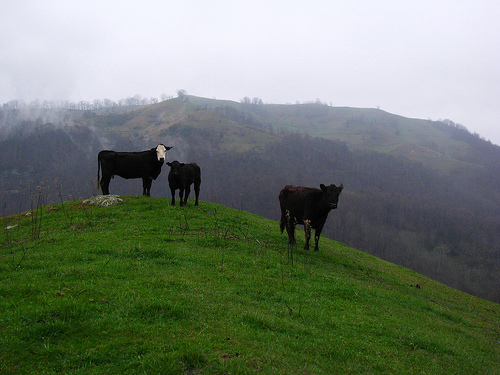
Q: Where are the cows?
A: Mountains.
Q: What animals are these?
A: Cows.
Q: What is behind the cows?
A: Mountain.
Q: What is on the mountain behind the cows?
A: Trees.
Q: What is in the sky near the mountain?
A: Fog.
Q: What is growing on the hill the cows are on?
A: Grass.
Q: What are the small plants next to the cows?
A: Trees.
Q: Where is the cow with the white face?
A: Left.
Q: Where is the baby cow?
A: Middle.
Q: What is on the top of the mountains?
A: Trees.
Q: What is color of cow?
A: Black.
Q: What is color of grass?
A: Green.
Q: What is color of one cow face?
A: White.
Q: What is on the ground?
A: Grass.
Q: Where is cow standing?
A: Hill.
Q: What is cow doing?
A: Standing.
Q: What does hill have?
A: Grass.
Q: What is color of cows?
A: Black.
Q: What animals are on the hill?
A: Cows.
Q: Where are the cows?
A: On a hill.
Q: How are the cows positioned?
A: Standing.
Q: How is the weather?
A: Foggy.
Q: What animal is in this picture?
A: Cows.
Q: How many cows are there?
A: Three.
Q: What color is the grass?
A: Green.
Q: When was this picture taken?
A: Daytime.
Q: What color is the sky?
A: Blue.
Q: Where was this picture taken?
A: A pasture.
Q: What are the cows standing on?
A: The top of a hill.